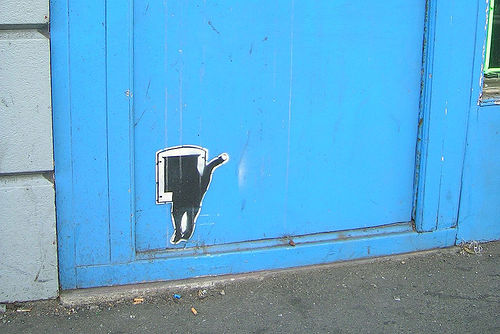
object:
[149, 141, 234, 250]
painting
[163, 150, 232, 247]
cat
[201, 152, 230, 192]
tail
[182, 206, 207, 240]
leg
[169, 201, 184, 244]
leg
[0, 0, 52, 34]
brick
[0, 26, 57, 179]
brick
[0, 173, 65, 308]
brick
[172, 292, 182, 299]
piece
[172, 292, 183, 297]
gum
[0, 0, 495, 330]
building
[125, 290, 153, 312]
cigarette butts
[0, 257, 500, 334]
ground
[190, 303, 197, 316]
cigarette butt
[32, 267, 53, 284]
marks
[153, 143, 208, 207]
white border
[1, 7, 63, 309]
wall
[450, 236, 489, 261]
decoration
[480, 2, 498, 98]
window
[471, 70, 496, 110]
corner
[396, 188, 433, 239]
corner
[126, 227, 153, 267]
corner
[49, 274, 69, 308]
corner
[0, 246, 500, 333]
street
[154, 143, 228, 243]
picture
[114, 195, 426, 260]
door frame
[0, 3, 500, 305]
wall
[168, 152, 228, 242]
cat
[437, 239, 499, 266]
garbage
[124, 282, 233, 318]
garbage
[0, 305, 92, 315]
garbage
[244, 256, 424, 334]
ground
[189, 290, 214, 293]
trash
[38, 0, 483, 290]
door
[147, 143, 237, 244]
backside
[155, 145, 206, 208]
pet door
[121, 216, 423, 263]
dirt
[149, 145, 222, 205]
opening